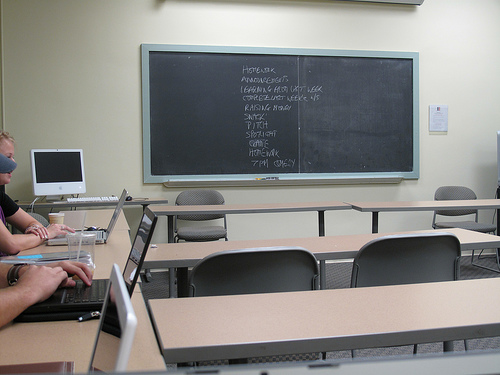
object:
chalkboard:
[141, 45, 419, 184]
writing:
[241, 68, 323, 166]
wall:
[0, 0, 499, 187]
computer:
[29, 148, 86, 194]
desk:
[0, 208, 171, 375]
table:
[145, 202, 352, 243]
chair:
[174, 190, 226, 241]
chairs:
[187, 246, 319, 296]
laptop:
[48, 189, 127, 245]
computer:
[15, 207, 158, 323]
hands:
[14, 265, 68, 301]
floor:
[141, 252, 500, 299]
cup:
[49, 213, 64, 224]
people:
[0, 260, 89, 328]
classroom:
[0, 0, 499, 375]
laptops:
[0, 263, 139, 374]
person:
[1, 131, 75, 254]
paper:
[430, 105, 449, 132]